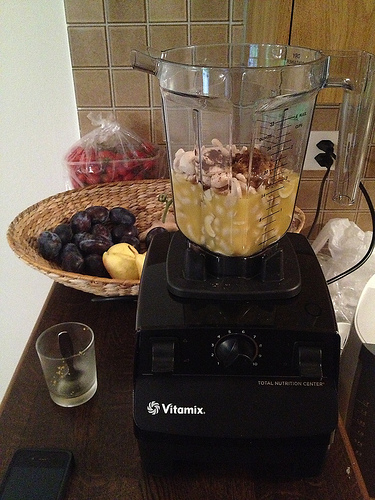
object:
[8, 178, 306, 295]
basket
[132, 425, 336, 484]
belong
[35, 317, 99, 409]
glass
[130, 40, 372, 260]
plastic pitcher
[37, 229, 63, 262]
purple grapes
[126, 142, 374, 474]
blender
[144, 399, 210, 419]
logo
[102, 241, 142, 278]
fruit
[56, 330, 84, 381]
spoon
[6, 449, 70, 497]
cellphone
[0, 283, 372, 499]
table